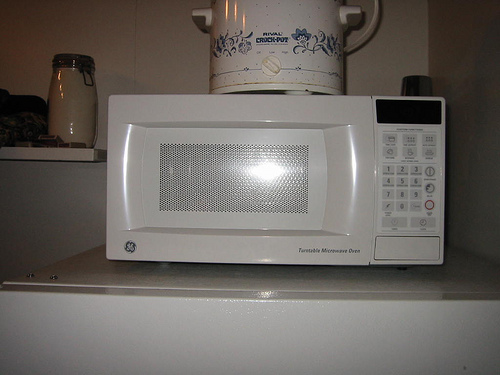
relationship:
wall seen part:
[445, 5, 498, 285] [464, 186, 478, 198]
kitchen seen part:
[4, 4, 498, 367] [228, 330, 244, 344]